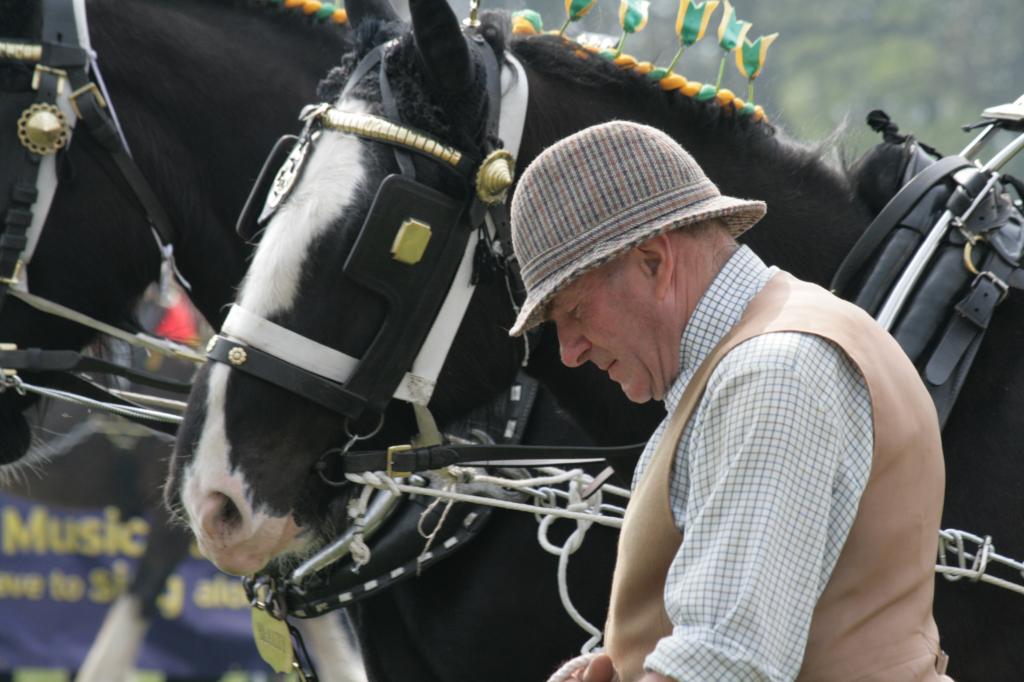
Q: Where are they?
A: In a parade.